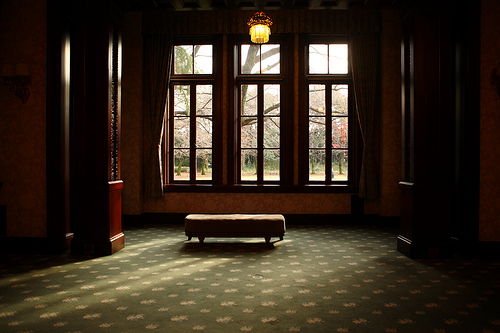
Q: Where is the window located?
A: In the room.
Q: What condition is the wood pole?
A: Polished.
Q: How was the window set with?
A: Three parts.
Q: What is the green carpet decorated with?
A: Yellow patterns.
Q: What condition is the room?
A: Dark.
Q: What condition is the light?
A: Dim.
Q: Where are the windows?
A: On the wall.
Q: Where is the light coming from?
A: The windows.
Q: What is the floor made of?
A: Carpet.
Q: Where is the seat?
A: In front of the windows.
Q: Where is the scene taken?
A: Inside the house.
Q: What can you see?
A: Window facing the lawn.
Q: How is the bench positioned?
A: In the middle, facing the window.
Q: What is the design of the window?
A: Rectangular and having panes.